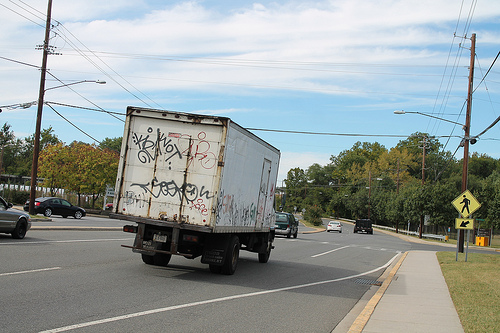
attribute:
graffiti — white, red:
[126, 124, 211, 208]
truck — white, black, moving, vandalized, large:
[116, 103, 282, 274]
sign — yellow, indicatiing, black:
[453, 218, 476, 231]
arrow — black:
[460, 219, 473, 229]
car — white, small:
[326, 218, 345, 234]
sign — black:
[452, 189, 483, 219]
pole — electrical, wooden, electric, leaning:
[463, 30, 472, 188]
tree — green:
[70, 144, 112, 180]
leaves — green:
[75, 149, 83, 156]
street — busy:
[271, 242, 397, 277]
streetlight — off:
[393, 105, 408, 120]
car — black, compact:
[28, 190, 88, 216]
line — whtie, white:
[317, 239, 354, 265]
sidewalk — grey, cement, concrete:
[402, 250, 441, 312]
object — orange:
[471, 232, 490, 249]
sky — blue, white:
[267, 97, 324, 116]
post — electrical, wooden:
[467, 51, 475, 128]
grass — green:
[462, 272, 490, 307]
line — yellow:
[385, 265, 398, 280]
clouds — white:
[279, 21, 316, 47]